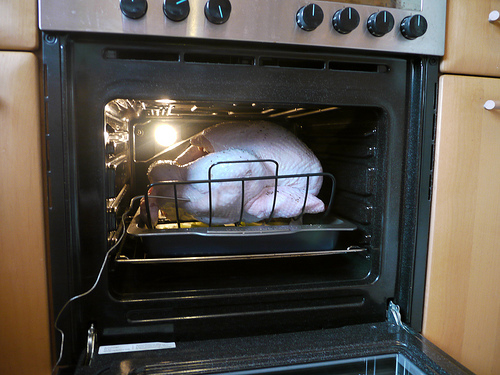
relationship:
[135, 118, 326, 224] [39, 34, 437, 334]
turkey in oven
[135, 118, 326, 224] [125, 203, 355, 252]
turkey in pan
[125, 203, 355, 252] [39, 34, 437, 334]
pan in oven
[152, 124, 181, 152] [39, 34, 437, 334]
light in oven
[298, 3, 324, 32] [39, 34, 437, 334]
knob for oven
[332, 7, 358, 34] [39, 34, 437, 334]
knob for oven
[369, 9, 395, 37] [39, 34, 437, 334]
knob for oven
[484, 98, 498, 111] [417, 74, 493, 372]
knob on cabinet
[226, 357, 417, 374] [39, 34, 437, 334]
window of oven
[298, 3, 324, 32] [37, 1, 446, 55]
knob on control panel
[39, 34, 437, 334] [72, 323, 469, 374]
oven has door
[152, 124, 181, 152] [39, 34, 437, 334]
light inside oven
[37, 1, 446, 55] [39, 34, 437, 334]
control panel for oven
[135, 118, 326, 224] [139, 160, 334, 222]
turkey on rack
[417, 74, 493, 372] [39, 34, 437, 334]
cabinet by oven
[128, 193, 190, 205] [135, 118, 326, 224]
thermometer in turkey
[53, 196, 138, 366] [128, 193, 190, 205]
cord for thermometer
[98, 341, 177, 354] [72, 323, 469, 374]
sticker on door